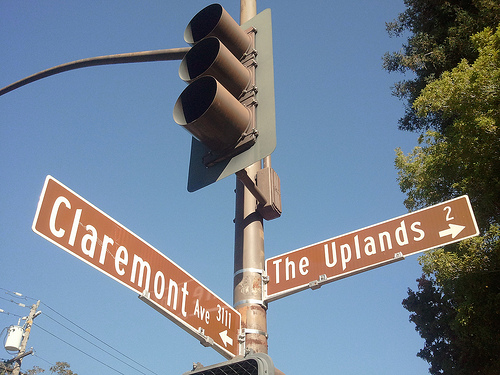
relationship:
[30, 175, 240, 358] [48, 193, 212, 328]
sign says claremont ave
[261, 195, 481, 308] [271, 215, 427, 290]
sign says uplands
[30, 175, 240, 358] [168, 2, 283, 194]
sign on stop light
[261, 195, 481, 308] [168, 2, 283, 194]
sign on stop light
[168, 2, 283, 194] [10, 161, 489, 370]
stop light at intersection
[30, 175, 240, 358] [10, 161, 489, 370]
sign at intersection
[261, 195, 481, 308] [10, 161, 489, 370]
sign at intersection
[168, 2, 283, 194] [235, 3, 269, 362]
stop light on pole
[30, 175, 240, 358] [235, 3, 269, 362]
sign on pole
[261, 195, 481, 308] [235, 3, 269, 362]
sign on pole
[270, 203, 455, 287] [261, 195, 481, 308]
lettering on sign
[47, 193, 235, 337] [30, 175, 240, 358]
lettering on sign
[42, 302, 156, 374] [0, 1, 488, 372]
wire goes across sky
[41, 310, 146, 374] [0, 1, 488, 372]
wire goes across sky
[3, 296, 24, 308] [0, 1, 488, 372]
wire goes across sky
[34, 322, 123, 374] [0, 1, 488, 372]
wire goes across sky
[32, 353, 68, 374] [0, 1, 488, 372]
wire goes across sky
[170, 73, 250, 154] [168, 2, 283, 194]
cover on stop light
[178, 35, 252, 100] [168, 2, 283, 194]
light on stop light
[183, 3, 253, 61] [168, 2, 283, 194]
light on stop light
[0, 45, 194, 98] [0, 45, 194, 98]
street lamp has street lamp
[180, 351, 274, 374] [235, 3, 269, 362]
walking signal on pole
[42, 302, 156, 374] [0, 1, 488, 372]
wire in sky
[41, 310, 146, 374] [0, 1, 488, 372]
wire in sky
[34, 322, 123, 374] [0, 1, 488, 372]
wire in sky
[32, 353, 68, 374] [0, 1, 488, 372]
wire in sky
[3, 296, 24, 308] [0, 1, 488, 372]
wire in sky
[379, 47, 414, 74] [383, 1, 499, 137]
leaves are on tree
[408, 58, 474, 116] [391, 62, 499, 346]
leaves are on tree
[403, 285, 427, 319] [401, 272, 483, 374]
leaves are on tree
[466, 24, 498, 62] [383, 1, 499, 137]
leaves are on tree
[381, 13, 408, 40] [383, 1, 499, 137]
leaves are on tree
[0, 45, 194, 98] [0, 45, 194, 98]
street lamp for street lamp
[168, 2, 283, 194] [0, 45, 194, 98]
stop light attached to street lamp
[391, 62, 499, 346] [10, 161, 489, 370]
tree near intersection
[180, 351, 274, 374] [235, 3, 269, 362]
walking signal attached to pole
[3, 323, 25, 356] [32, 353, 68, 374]
box attached to wire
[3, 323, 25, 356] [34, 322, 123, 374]
box attached to wire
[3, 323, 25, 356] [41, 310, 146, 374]
box attached to wire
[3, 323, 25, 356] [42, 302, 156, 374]
box attached to wire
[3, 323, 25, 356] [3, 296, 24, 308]
box attached to wire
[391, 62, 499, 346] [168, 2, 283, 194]
tree right of stop light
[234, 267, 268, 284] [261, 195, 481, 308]
fastener attaches sign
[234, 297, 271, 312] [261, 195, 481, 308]
fastener attaches sign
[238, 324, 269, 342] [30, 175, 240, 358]
fastener attaches sign